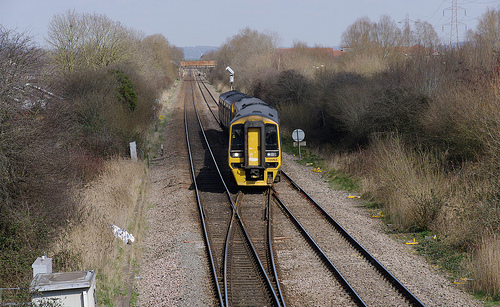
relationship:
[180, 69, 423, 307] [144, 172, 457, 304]
rails rested on gravel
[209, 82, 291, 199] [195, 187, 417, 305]
train on tracks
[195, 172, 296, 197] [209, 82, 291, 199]
tracks beneath train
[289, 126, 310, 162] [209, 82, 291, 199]
sign next to train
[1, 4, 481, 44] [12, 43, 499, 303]
gray sky above land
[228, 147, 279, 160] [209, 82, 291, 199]
lights on front train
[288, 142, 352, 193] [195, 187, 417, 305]
green grass next to tracks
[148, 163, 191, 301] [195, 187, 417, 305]
gravel next to tracks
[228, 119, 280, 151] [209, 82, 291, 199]
windows on front train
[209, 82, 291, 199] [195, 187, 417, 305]
train traveling down tracks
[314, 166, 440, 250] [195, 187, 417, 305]
debris on side tracks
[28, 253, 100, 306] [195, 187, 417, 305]
box on side tracks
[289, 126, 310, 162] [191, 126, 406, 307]
sign on side rail tracks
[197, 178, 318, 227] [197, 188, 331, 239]
smoke on top train tracks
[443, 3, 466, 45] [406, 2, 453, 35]
pole support power line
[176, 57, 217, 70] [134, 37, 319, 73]
bridge in background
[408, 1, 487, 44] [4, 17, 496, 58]
power lines in background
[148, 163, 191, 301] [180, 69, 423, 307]
gravel on ground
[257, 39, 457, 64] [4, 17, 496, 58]
houses in background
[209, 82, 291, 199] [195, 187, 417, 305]
train switching tracks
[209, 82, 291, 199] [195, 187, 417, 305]
train switching to other tracks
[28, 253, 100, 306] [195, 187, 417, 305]
control box for track switch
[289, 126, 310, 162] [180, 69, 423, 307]
sign of railroad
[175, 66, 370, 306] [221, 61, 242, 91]
railroad warning light